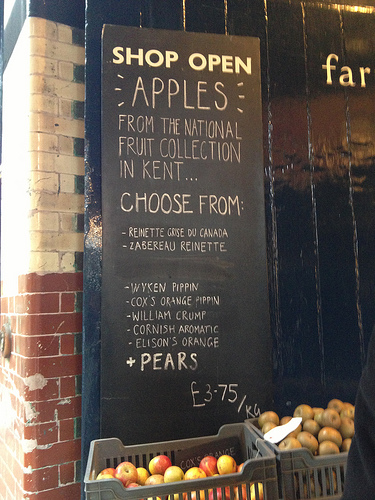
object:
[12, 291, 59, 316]
brick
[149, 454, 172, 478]
apple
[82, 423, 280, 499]
bin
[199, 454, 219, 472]
apple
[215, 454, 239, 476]
apple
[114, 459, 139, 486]
apple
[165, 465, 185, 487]
apple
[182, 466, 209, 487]
apple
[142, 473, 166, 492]
apple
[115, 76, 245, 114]
apples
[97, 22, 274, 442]
poster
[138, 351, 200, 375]
pears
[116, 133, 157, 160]
fruit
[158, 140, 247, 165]
collection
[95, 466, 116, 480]
apples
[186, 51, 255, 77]
open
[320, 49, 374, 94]
far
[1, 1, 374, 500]
building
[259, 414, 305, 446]
tag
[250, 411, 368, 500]
bins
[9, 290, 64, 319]
brick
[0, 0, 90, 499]
wall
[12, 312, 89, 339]
brick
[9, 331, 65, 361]
brick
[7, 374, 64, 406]
brick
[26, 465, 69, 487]
brick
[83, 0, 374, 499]
wall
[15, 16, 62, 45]
brick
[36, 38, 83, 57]
brick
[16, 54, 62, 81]
brick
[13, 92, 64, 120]
brick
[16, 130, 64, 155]
brick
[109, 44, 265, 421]
writing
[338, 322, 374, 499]
sleeve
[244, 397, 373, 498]
crate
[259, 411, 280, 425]
pears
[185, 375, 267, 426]
price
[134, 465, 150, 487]
apple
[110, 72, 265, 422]
chalk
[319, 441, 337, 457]
pear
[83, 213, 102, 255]
spot